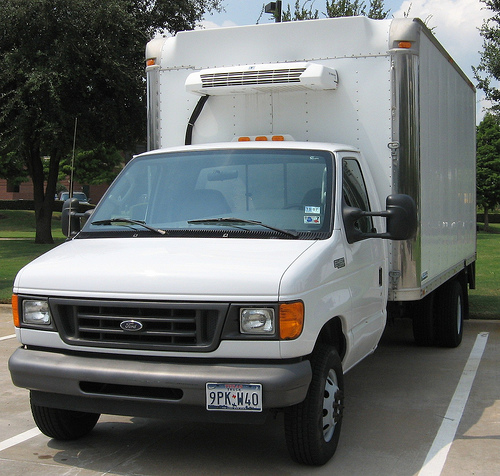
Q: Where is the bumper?
A: On car.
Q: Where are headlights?
A: On vehicle.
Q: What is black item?
A: Tire.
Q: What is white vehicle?
A: Truck.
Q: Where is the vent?
A: Truck.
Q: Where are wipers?
A: On truck.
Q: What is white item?
A: Line.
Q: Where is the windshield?
A: On truck.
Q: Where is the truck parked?
A: In a parking lot.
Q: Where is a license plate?
A: On front of the truck.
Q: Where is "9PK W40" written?
A: On license plate.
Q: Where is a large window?
A: On the truck.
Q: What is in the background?
A: Trees.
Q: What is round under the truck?
A: Tires.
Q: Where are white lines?
A: On the pavement.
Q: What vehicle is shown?
A: Truck.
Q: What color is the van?
A: White.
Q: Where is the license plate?
A: On the van's bumper.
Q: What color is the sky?
A: Blue.